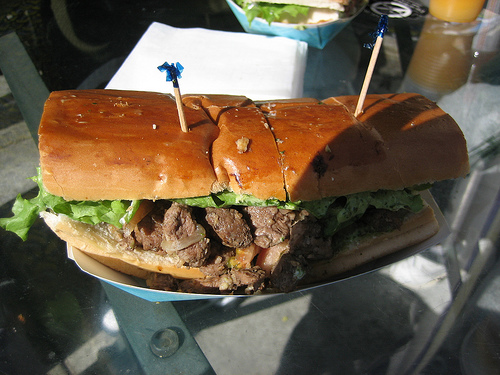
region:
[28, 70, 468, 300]
this is a sandwich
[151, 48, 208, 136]
this is a tooth pick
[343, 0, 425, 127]
this is a tooth pick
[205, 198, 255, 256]
this is a piece of meat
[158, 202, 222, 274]
this is a piece of meat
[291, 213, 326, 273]
this is a piece of meat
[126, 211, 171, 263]
this is a piece of meat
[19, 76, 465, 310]
this is a sandwich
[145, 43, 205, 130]
this is a tooth pick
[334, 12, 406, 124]
this is a tooth pick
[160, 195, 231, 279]
this is a piece of meat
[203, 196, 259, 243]
this is a piece of meat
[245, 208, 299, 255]
this is a piece of meat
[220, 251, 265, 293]
this is a piece of meat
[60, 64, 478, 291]
the sandwich is a sub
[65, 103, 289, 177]
the sandwich is sliced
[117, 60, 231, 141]
this is a toothpick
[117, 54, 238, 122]
the toothpick is wood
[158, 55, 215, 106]
the toothpick is blue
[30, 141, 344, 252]
the sandwich has beef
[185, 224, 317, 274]
the meat is brown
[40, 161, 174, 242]
the sandwich has lettuce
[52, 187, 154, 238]
the lettuce is green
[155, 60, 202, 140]
tooth pic on a bun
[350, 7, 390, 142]
tooth pic on a bun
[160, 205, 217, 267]
meat on a bun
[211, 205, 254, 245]
meat on a bun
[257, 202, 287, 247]
meat on a bun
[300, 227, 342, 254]
meat on a bun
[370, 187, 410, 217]
lettuce on a bun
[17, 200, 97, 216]
lettuce on a bun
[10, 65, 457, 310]
food on a basket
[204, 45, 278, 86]
napkins on a table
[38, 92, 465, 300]
a big meat sandwich